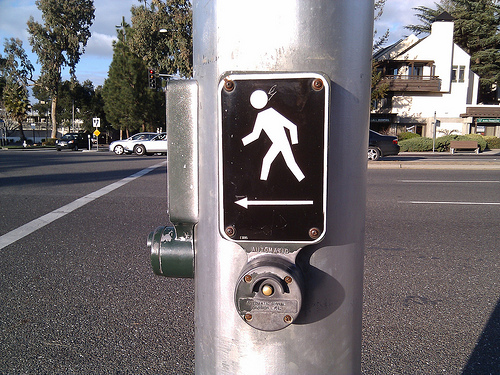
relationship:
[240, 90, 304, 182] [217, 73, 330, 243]
figure on crosswalk sign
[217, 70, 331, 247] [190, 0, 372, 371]
crosswalk sign on pole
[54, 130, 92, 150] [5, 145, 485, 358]
car stopped on street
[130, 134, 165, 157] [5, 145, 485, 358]
car on street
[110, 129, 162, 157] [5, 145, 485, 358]
car on street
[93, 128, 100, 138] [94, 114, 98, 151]
traffic sign on pole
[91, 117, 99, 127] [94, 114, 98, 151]
traffic sign on pole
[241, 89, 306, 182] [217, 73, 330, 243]
figure walking on crosswalk sign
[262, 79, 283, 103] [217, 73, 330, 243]
writing on crosswalk sign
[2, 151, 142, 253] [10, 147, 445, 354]
paint on ground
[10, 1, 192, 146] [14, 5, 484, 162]
trees in back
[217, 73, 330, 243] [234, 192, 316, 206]
crosswalk sign directing pedestrians to follow arrow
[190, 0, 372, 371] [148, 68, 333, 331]
pole with traffic equipment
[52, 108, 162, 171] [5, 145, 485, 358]
traffic on street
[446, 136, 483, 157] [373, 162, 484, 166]
bench by curb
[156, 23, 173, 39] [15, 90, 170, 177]
street light above area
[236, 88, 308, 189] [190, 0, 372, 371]
symbol on a pole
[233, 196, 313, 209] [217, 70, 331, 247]
arrow on a crosswalk sign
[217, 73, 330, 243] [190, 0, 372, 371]
crosswalk sign on a pole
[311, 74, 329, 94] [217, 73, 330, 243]
screw on a crosswalk sign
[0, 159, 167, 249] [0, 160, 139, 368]
line on ground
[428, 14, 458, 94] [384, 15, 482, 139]
chimney on side of house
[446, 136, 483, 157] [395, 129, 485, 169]
bench by a bus stop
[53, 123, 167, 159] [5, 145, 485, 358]
cars moving along a street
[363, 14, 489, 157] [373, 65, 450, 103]
house has balcony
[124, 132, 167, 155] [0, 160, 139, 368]
car driving on ground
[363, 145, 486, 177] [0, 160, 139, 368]
median in middle of ground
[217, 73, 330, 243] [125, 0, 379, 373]
crosswalk sign on pole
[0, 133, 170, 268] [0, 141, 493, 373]
line on street